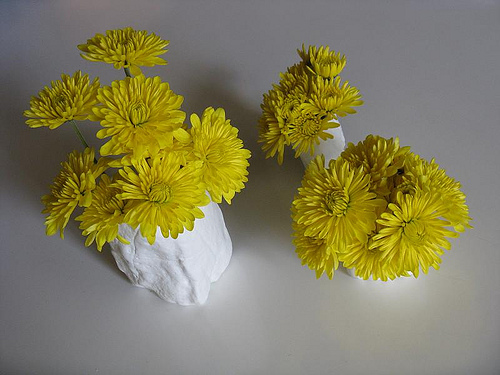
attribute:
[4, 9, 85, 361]
table — white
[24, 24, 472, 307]
flowers — yellow, blooming, bunched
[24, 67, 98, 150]
flower — yellow, large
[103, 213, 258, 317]
vase — clay, white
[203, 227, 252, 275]
clay — white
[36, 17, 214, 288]
bunch — biggest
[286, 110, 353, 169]
vase — white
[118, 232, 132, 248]
petal — yellow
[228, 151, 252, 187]
petals — yellow